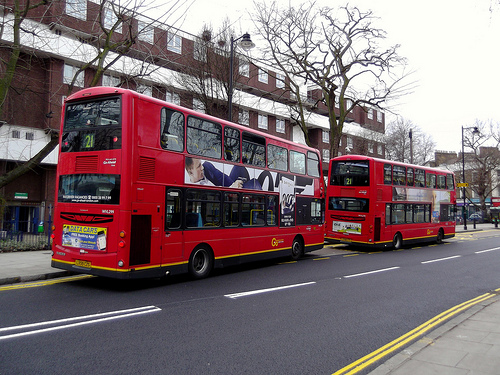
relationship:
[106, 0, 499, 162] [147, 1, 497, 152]
clouds in sky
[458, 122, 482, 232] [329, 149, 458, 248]
light post behind bus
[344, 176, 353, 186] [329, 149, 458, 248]
21 on bus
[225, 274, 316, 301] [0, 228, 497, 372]
line painted on street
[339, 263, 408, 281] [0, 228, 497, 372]
line painted on street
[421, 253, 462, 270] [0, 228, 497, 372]
line painted on street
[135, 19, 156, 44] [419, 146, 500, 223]
window on building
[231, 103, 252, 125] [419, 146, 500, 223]
window on building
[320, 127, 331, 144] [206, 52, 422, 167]
window on building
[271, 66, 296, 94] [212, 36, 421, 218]
window on building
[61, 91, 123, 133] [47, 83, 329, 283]
window on bus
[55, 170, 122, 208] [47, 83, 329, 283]
window on bus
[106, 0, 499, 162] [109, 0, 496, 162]
clouds in sky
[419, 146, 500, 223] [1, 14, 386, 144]
building with trim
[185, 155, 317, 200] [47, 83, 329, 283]
advertisement on bus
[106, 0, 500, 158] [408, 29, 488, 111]
clouds in sky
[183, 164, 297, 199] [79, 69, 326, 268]
advertisement on bus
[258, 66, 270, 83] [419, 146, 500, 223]
window in building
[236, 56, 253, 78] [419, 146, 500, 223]
window in building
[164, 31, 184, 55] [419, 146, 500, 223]
window in building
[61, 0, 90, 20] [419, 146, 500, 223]
window in building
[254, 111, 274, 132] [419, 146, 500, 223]
window in building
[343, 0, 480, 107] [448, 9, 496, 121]
sky is full of clouds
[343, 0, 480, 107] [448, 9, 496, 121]
sky holds clouds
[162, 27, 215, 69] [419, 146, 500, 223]
window on building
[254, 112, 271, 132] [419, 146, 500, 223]
window on building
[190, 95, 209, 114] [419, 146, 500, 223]
window on building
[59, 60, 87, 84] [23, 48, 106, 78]
window on building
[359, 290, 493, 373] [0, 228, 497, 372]
curb next to street